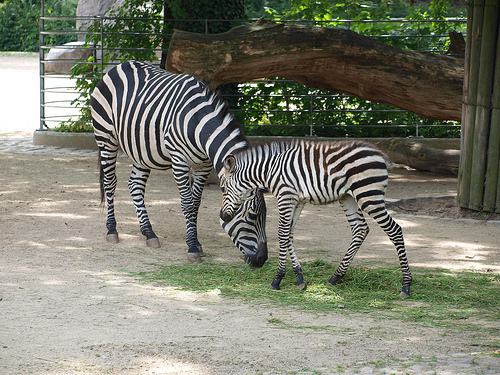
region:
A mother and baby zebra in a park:
[5, 23, 487, 365]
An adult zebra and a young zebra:
[69, 61, 431, 286]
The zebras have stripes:
[87, 69, 397, 301]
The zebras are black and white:
[78, 62, 438, 302]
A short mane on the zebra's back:
[201, 86, 245, 141]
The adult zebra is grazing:
[77, 62, 318, 269]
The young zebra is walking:
[217, 133, 436, 307]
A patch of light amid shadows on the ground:
[98, 269, 225, 317]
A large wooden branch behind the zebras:
[164, 22, 476, 135]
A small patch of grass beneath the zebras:
[151, 222, 479, 318]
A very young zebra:
[219, 137, 414, 297]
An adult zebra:
[91, 58, 266, 270]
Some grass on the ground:
[131, 252, 496, 334]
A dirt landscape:
[1, 54, 496, 372]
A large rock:
[42, 39, 94, 73]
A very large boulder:
[76, 3, 167, 69]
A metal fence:
[41, 13, 468, 139]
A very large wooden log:
[163, 15, 464, 120]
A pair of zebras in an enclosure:
[86, 55, 416, 300]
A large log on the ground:
[376, 135, 463, 178]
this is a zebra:
[211, 146, 446, 295]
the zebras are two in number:
[81, 68, 390, 250]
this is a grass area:
[349, 265, 364, 317]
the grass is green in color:
[361, 268, 380, 298]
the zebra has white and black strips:
[285, 160, 339, 190]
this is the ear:
[221, 155, 242, 180]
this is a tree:
[13, 5, 35, 27]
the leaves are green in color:
[16, 10, 33, 34]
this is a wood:
[266, 29, 425, 86]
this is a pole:
[471, 65, 483, 246]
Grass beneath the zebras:
[167, 253, 494, 311]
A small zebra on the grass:
[221, 153, 412, 295]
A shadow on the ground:
[6, 154, 104, 351]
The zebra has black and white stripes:
[259, 158, 386, 189]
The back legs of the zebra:
[328, 195, 410, 295]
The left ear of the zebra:
[225, 155, 235, 175]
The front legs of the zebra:
[272, 195, 308, 292]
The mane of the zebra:
[197, 85, 244, 146]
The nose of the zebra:
[257, 245, 267, 262]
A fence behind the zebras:
[40, 20, 460, 138]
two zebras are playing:
[37, 23, 442, 315]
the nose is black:
[235, 241, 272, 276]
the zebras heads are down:
[203, 128, 288, 273]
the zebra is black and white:
[76, 62, 245, 206]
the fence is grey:
[23, 5, 178, 125]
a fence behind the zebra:
[34, 3, 230, 128]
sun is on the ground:
[424, 230, 491, 300]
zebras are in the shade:
[42, 54, 422, 313]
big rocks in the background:
[31, 2, 158, 92]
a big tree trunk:
[123, 9, 449, 154]